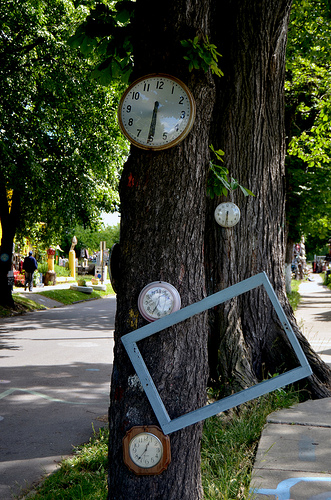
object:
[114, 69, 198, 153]
clock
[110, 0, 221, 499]
tree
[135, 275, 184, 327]
clock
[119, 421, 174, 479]
clock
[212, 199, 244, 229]
clock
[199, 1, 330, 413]
tree